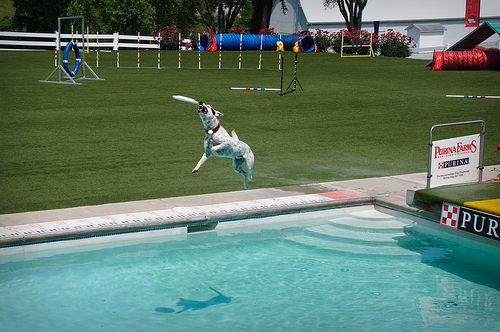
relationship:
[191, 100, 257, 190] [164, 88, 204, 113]
dog catching a frisbee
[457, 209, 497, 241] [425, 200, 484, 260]
white letters in sign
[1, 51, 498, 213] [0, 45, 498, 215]
green grass in field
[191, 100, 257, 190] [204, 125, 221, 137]
dog with red necklace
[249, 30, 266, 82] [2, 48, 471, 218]
pole in ground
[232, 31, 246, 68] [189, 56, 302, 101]
pole in ground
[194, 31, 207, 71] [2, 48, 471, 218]
pole in ground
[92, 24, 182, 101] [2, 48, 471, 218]
pole in ground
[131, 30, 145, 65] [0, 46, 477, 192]
pole in ground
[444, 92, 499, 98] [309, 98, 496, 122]
pole in ground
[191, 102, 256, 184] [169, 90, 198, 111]
dog catching frisbee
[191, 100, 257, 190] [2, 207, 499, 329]
dog jumping over pool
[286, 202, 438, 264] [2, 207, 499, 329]
steps in pool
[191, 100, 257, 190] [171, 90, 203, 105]
dog catching frisbee